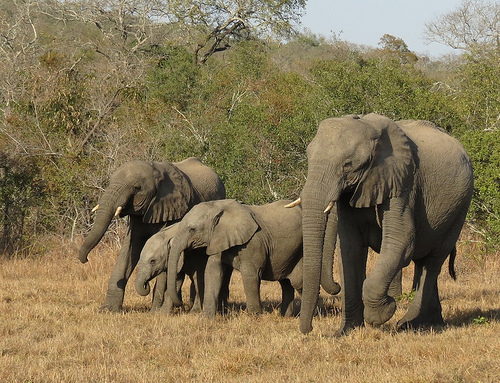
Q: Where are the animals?
A: In the grass.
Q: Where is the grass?
A: Under the elephants.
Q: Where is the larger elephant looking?
A: The larger elephant is looking in front.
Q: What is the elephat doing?
A: The elephant is raising its head.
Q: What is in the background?
A: A large forest.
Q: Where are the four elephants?
A: The four elephants are in the savanna.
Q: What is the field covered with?
A: The field is covered with dry grass.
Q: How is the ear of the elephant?
A: The ear is large in size.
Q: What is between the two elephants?
A: A baby elephant.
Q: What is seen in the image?
A: Elephants walking.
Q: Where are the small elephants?
A: In the middle.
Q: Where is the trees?
A: To the left of the elephants.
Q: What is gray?
A: Elephants.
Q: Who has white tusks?
A: The elephants.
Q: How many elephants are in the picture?
A: Four.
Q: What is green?
A: Trees.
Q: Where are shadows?
A: On the grass.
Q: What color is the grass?
A: Light brown.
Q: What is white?
A: Elephant's tusks.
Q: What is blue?
A: The sky.